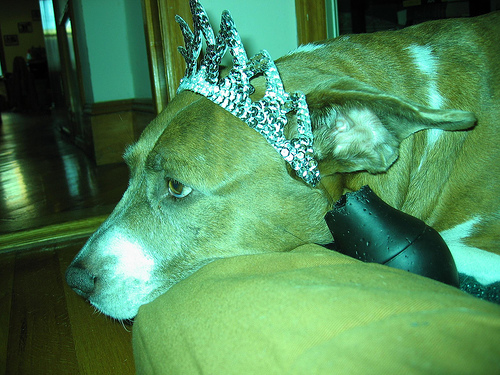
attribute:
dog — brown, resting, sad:
[65, 8, 499, 321]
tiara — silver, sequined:
[173, 1, 321, 186]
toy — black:
[326, 181, 461, 304]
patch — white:
[409, 42, 449, 175]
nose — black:
[65, 267, 94, 299]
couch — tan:
[130, 241, 500, 373]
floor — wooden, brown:
[2, 105, 135, 374]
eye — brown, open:
[168, 178, 194, 199]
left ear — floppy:
[309, 79, 477, 176]